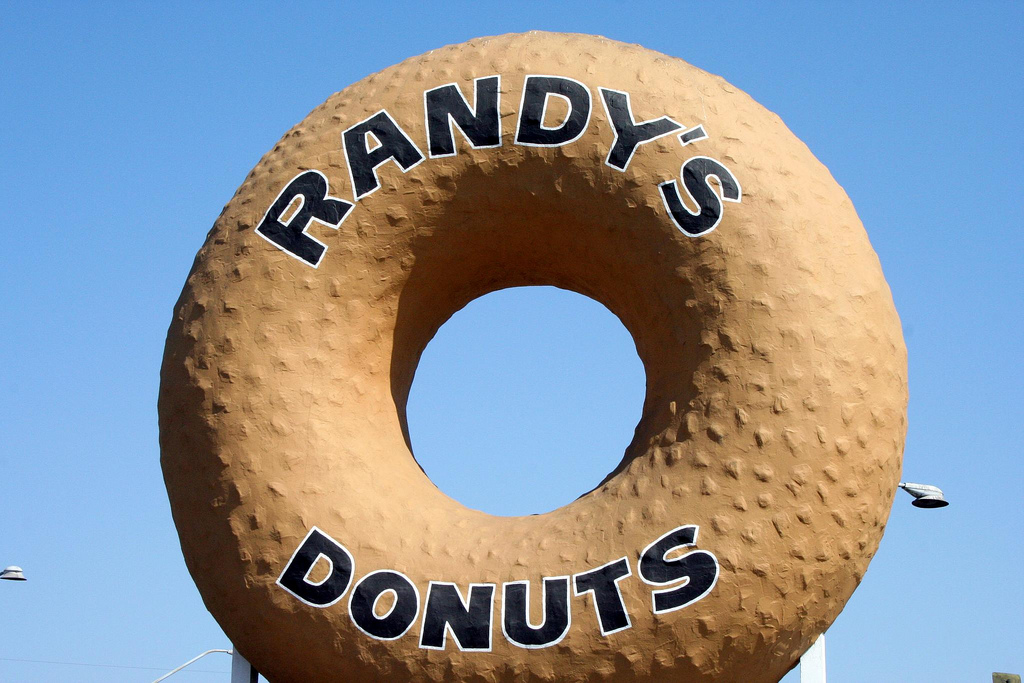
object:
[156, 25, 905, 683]
donut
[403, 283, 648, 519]
sky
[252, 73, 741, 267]
randy's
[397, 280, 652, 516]
donut hole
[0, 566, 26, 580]
street light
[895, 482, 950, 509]
street light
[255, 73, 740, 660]
letters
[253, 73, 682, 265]
randy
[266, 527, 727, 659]
donuts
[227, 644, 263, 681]
pole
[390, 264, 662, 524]
shadow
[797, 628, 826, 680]
post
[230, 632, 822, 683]
supports